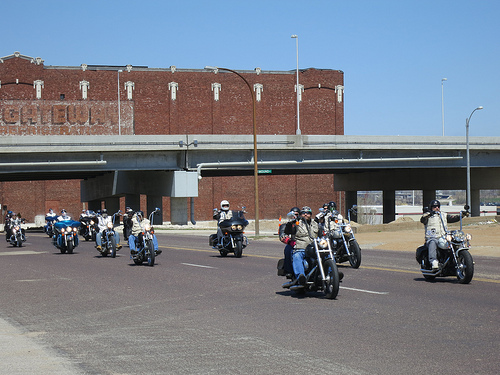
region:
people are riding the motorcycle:
[4, 201, 473, 298]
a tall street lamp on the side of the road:
[201, 65, 261, 237]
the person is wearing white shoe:
[420, 198, 469, 270]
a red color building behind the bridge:
[4, 52, 494, 229]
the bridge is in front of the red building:
[0, 53, 492, 233]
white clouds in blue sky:
[28, 2, 92, 43]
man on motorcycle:
[207, 188, 261, 262]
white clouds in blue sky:
[172, 18, 224, 53]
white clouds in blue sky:
[45, 1, 75, 19]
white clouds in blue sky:
[422, 29, 460, 56]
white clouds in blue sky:
[395, 26, 466, 81]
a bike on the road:
[279, 205, 337, 291]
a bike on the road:
[416, 190, 466, 290]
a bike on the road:
[302, 187, 377, 284]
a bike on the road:
[197, 175, 247, 271]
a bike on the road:
[139, 205, 173, 275]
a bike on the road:
[90, 198, 117, 255]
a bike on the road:
[54, 211, 94, 262]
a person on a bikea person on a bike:
[287, 199, 332, 309]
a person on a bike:
[422, 200, 476, 297]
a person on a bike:
[211, 193, 246, 259]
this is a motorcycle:
[412, 193, 473, 290]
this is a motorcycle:
[280, 196, 339, 308]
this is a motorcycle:
[325, 203, 365, 280]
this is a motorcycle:
[207, 193, 250, 257]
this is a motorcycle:
[125, 208, 163, 268]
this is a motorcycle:
[91, 207, 122, 263]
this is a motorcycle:
[46, 205, 85, 250]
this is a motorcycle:
[3, 208, 32, 259]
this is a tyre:
[312, 251, 341, 301]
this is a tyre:
[451, 250, 480, 285]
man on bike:
[217, 193, 259, 250]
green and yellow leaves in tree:
[425, 48, 450, 66]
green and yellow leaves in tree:
[368, 51, 426, 99]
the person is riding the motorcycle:
[209, 198, 249, 257]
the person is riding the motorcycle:
[276, 205, 343, 299]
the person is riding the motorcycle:
[415, 199, 475, 283]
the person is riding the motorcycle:
[316, 200, 361, 266]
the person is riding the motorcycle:
[122, 205, 162, 267]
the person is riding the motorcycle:
[86, 209, 121, 256]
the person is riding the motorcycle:
[52, 209, 78, 252]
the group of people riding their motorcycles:
[5, 197, 475, 299]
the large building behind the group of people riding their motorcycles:
[0, 52, 474, 299]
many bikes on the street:
[0, 143, 495, 363]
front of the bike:
[293, 255, 366, 302]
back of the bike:
[401, 241, 444, 298]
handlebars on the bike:
[422, 205, 476, 239]